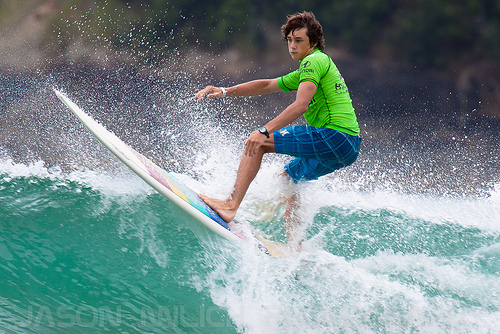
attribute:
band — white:
[216, 85, 228, 101]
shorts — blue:
[272, 126, 362, 181]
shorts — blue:
[271, 121, 363, 185]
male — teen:
[190, 11, 365, 221]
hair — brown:
[282, 12, 327, 47]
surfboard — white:
[49, 85, 272, 257]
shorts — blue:
[268, 127, 364, 187]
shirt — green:
[291, 61, 419, 135]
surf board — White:
[53, 86, 295, 262]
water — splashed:
[21, 22, 493, 331]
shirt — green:
[264, 44, 380, 147]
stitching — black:
[319, 60, 331, 90]